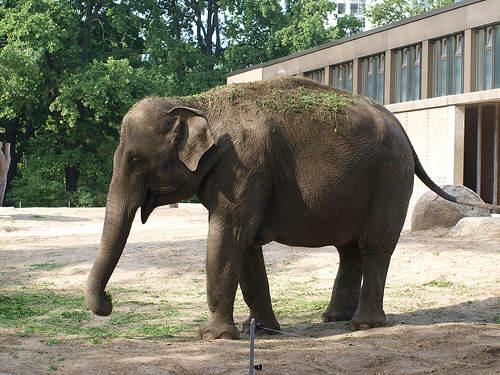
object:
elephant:
[85, 75, 499, 339]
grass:
[278, 81, 347, 129]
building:
[355, 0, 499, 110]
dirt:
[129, 270, 199, 366]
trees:
[31, 11, 178, 99]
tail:
[414, 156, 499, 226]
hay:
[112, 295, 115, 296]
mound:
[0, 324, 498, 367]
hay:
[273, 346, 305, 356]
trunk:
[88, 199, 137, 320]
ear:
[162, 105, 215, 172]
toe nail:
[201, 330, 211, 339]